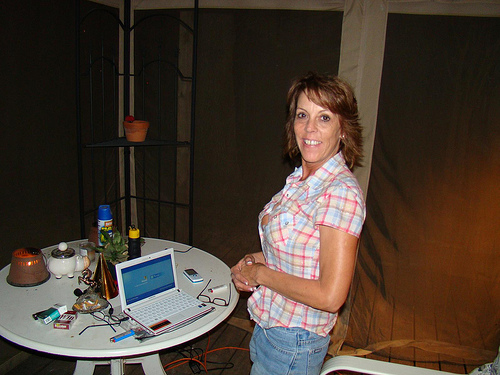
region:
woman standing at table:
[77, 100, 404, 330]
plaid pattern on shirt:
[283, 209, 320, 256]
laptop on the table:
[132, 252, 212, 333]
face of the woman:
[282, 94, 356, 165]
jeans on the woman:
[252, 352, 284, 370]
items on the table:
[12, 212, 93, 337]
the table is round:
[29, 218, 232, 358]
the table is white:
[7, 328, 63, 350]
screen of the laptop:
[121, 260, 181, 297]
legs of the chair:
[59, 348, 164, 373]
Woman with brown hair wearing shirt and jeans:
[229, 67, 367, 373]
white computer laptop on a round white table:
[111, 244, 216, 336]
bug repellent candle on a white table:
[2, 240, 53, 291]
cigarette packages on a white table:
[31, 300, 80, 337]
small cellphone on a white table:
[181, 264, 203, 286]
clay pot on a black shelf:
[119, 107, 154, 149]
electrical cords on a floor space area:
[162, 336, 250, 373]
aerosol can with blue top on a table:
[94, 200, 119, 251]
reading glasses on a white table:
[79, 308, 131, 339]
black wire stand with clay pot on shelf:
[68, 0, 202, 244]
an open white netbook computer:
[114, 248, 212, 336]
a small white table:
[1, 232, 239, 373]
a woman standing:
[229, 72, 366, 373]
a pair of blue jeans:
[248, 321, 327, 373]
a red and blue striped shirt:
[247, 151, 366, 334]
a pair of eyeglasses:
[195, 278, 232, 308]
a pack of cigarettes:
[52, 310, 76, 330]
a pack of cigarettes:
[33, 305, 65, 325]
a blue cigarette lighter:
[109, 328, 136, 343]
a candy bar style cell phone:
[183, 266, 202, 283]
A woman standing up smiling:
[225, 71, 382, 373]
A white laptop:
[107, 249, 214, 330]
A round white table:
[13, 230, 249, 372]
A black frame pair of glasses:
[195, 278, 238, 307]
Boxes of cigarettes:
[28, 303, 80, 334]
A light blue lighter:
[107, 332, 135, 344]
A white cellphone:
[178, 260, 209, 287]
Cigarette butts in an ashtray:
[67, 288, 113, 315]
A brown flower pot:
[120, 115, 156, 147]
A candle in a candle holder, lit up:
[6, 244, 57, 286]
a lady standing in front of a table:
[244, 77, 351, 373]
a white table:
[0, 224, 245, 351]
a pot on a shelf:
[125, 120, 145, 135]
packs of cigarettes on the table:
[36, 301, 73, 333]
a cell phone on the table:
[181, 265, 198, 282]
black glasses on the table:
[192, 278, 232, 307]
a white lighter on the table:
[206, 281, 228, 291]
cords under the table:
[174, 343, 230, 366]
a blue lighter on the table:
[108, 328, 133, 337]